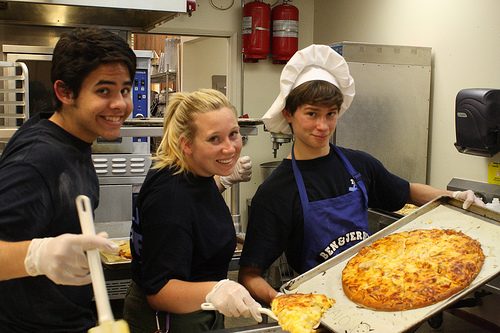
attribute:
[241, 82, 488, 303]
boy — smiling, young, teenager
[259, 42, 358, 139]
hat — white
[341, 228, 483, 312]
pizza — round, crispy, fresh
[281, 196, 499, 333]
tray — metal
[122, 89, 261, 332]
girl — young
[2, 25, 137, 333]
boy — smiling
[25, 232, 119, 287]
glove — plastic, latex, rubber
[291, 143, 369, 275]
apron — blue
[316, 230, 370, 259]
logo — white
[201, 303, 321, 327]
spatula — plastic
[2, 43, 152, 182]
oven — large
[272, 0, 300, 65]
fire extinguisher — red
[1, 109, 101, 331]
shirt — dirty